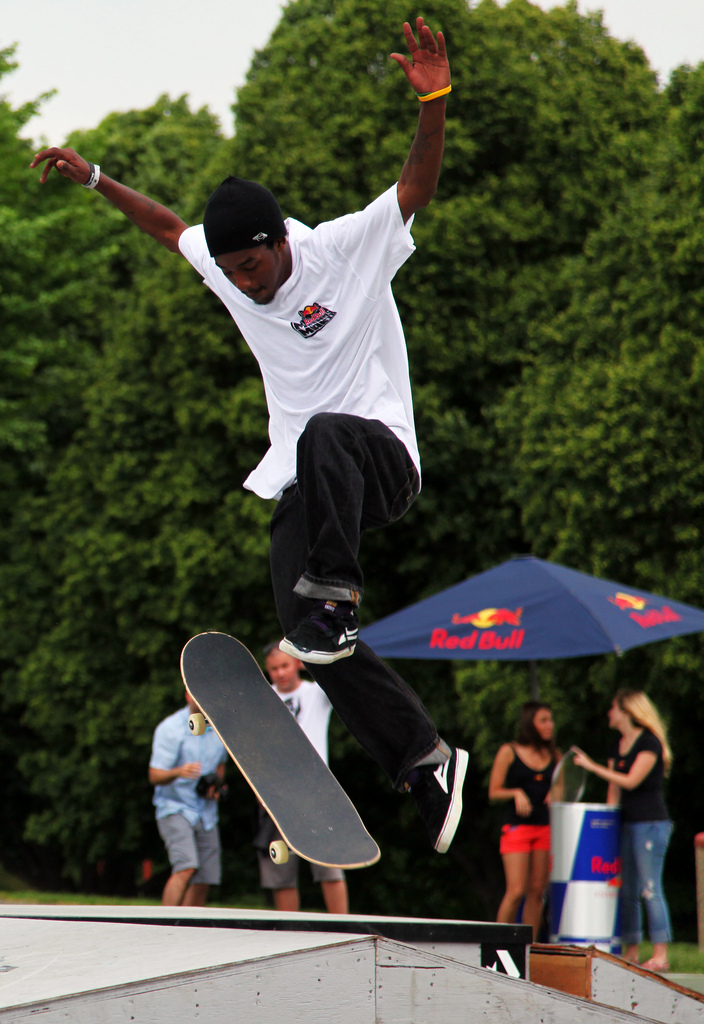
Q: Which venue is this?
A: This is a field.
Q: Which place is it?
A: It is a field.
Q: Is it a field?
A: Yes, it is a field.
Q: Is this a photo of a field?
A: Yes, it is showing a field.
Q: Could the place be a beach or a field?
A: It is a field.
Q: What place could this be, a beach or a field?
A: It is a field.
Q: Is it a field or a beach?
A: It is a field.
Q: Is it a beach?
A: No, it is a field.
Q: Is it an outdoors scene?
A: Yes, it is outdoors.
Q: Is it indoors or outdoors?
A: It is outdoors.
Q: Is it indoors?
A: No, it is outdoors.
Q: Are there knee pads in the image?
A: No, there are no knee pads.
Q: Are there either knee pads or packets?
A: No, there are no knee pads or packets.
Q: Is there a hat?
A: Yes, there is a hat.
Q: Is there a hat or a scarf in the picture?
A: Yes, there is a hat.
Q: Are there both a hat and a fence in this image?
A: No, there is a hat but no fences.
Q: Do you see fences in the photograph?
A: No, there are no fences.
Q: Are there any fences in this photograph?
A: No, there are no fences.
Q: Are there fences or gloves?
A: No, there are no fences or gloves.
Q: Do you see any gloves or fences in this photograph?
A: No, there are no fences or gloves.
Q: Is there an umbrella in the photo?
A: Yes, there is an umbrella.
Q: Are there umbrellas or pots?
A: Yes, there is an umbrella.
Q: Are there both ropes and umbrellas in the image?
A: No, there is an umbrella but no ropes.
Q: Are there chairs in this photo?
A: No, there are no chairs.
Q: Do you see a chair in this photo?
A: No, there are no chairs.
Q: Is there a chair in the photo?
A: No, there are no chairs.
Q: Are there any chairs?
A: No, there are no chairs.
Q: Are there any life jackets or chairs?
A: No, there are no chairs or life jackets.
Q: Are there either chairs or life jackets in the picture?
A: No, there are no chairs or life jackets.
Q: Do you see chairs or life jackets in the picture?
A: No, there are no chairs or life jackets.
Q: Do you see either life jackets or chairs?
A: No, there are no chairs or life jackets.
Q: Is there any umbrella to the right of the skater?
A: Yes, there is an umbrella to the right of the skater.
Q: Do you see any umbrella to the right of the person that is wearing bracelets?
A: Yes, there is an umbrella to the right of the skater.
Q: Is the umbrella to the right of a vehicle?
A: No, the umbrella is to the right of a skater.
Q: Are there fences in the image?
A: No, there are no fences.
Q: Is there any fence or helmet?
A: No, there are no fences or helmets.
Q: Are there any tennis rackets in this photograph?
A: No, there are no tennis rackets.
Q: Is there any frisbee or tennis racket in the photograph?
A: No, there are no rackets or frisbees.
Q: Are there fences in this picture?
A: No, there are no fences.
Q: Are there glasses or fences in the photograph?
A: No, there are no fences or glasses.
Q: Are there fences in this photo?
A: No, there are no fences.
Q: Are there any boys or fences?
A: No, there are no fences or boys.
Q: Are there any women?
A: Yes, there is a woman.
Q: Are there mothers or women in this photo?
A: Yes, there is a woman.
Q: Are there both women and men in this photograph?
A: Yes, there are both a woman and men.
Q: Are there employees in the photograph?
A: No, there are no employees.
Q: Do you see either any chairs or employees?
A: No, there are no employees or chairs.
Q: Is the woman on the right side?
A: Yes, the woman is on the right of the image.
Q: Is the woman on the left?
A: No, the woman is on the right of the image.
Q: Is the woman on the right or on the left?
A: The woman is on the right of the image.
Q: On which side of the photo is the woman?
A: The woman is on the right of the image.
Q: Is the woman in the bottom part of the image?
A: Yes, the woman is in the bottom of the image.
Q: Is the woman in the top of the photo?
A: No, the woman is in the bottom of the image.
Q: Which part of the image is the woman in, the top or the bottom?
A: The woman is in the bottom of the image.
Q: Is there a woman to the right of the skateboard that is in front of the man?
A: Yes, there is a woman to the right of the skateboard.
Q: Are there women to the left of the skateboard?
A: No, the woman is to the right of the skateboard.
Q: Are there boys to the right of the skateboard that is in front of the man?
A: No, there is a woman to the right of the skateboard.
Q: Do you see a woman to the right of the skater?
A: Yes, there is a woman to the right of the skater.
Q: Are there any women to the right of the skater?
A: Yes, there is a woman to the right of the skater.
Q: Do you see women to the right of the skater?
A: Yes, there is a woman to the right of the skater.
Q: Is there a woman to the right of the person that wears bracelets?
A: Yes, there is a woman to the right of the skater.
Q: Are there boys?
A: No, there are no boys.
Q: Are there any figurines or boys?
A: No, there are no boys or figurines.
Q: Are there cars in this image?
A: No, there are no cars.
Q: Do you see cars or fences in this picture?
A: No, there are no cars or fences.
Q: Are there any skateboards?
A: Yes, there is a skateboard.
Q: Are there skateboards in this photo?
A: Yes, there is a skateboard.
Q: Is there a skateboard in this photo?
A: Yes, there is a skateboard.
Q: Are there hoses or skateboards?
A: Yes, there is a skateboard.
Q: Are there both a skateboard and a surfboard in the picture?
A: No, there is a skateboard but no surfboards.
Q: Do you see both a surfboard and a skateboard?
A: No, there is a skateboard but no surfboards.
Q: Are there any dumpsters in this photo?
A: No, there are no dumpsters.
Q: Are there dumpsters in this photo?
A: No, there are no dumpsters.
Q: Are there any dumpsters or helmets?
A: No, there are no dumpsters or helmets.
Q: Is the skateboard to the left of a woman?
A: Yes, the skateboard is to the left of a woman.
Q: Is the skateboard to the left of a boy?
A: No, the skateboard is to the left of a woman.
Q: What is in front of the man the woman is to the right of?
A: The skateboard is in front of the man.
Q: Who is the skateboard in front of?
A: The skateboard is in front of the man.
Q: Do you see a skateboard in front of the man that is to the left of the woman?
A: Yes, there is a skateboard in front of the man.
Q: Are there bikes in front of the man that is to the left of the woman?
A: No, there is a skateboard in front of the man.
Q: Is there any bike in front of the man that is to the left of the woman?
A: No, there is a skateboard in front of the man.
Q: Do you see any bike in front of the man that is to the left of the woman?
A: No, there is a skateboard in front of the man.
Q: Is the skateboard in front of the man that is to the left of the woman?
A: Yes, the skateboard is in front of the man.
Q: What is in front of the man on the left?
A: The skateboard is in front of the man.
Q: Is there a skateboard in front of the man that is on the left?
A: Yes, there is a skateboard in front of the man.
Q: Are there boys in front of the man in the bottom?
A: No, there is a skateboard in front of the man.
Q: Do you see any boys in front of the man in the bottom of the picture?
A: No, there is a skateboard in front of the man.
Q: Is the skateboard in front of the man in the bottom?
A: Yes, the skateboard is in front of the man.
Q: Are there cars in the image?
A: No, there are no cars.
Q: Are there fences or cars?
A: No, there are no cars or fences.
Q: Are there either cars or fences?
A: No, there are no cars or fences.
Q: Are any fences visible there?
A: No, there are no fences.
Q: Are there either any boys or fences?
A: No, there are no fences or boys.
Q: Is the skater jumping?
A: Yes, the skater is jumping.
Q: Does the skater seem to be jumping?
A: Yes, the skater is jumping.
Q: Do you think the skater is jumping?
A: Yes, the skater is jumping.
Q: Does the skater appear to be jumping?
A: Yes, the skater is jumping.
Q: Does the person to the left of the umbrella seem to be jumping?
A: Yes, the skater is jumping.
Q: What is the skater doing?
A: The skater is jumping.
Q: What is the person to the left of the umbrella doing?
A: The skater is jumping.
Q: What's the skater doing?
A: The skater is jumping.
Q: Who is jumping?
A: The skater is jumping.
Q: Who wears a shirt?
A: The skater wears a shirt.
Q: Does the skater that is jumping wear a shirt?
A: Yes, the skater wears a shirt.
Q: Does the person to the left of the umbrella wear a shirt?
A: Yes, the skater wears a shirt.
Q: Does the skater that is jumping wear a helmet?
A: No, the skater wears a shirt.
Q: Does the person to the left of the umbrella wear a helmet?
A: No, the skater wears a shirt.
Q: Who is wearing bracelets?
A: The skater is wearing bracelets.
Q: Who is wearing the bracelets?
A: The skater is wearing bracelets.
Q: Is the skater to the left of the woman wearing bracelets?
A: Yes, the skater is wearing bracelets.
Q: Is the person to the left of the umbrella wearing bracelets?
A: Yes, the skater is wearing bracelets.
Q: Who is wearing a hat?
A: The skater is wearing a hat.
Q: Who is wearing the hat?
A: The skater is wearing a hat.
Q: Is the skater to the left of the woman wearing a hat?
A: Yes, the skater is wearing a hat.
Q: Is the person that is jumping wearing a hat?
A: Yes, the skater is wearing a hat.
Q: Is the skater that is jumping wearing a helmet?
A: No, the skater is wearing a hat.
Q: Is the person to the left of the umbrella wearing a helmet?
A: No, the skater is wearing a hat.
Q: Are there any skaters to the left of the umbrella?
A: Yes, there is a skater to the left of the umbrella.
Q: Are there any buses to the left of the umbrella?
A: No, there is a skater to the left of the umbrella.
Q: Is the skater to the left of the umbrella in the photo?
A: Yes, the skater is to the left of the umbrella.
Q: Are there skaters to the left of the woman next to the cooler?
A: Yes, there is a skater to the left of the woman.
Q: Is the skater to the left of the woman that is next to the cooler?
A: Yes, the skater is to the left of the woman.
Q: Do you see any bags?
A: No, there are no bags.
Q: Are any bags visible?
A: No, there are no bags.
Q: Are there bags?
A: No, there are no bags.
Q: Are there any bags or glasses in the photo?
A: No, there are no bags or glasses.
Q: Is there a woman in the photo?
A: Yes, there is a woman.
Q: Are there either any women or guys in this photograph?
A: Yes, there is a woman.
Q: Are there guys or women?
A: Yes, there is a woman.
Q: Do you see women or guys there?
A: Yes, there is a woman.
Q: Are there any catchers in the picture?
A: No, there are no catchers.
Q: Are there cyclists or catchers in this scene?
A: No, there are no catchers or cyclists.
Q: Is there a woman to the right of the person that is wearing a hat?
A: Yes, there is a woman to the right of the skater.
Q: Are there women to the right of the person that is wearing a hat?
A: Yes, there is a woman to the right of the skater.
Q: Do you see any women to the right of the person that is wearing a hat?
A: Yes, there is a woman to the right of the skater.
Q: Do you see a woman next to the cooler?
A: Yes, there is a woman next to the cooler.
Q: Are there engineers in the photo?
A: No, there are no engineers.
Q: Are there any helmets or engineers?
A: No, there are no engineers or helmets.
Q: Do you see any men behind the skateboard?
A: Yes, there is a man behind the skateboard.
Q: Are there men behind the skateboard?
A: Yes, there is a man behind the skateboard.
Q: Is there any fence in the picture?
A: No, there are no fences.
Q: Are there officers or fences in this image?
A: No, there are no fences or officers.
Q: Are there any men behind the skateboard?
A: Yes, there is a man behind the skateboard.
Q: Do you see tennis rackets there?
A: No, there are no tennis rackets.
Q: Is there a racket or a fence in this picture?
A: No, there are no rackets or fences.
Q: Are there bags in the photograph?
A: No, there are no bags.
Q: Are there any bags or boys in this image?
A: No, there are no bags or boys.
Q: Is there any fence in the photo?
A: No, there are no fences.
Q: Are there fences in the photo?
A: No, there are no fences.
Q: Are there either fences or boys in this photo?
A: No, there are no fences or boys.